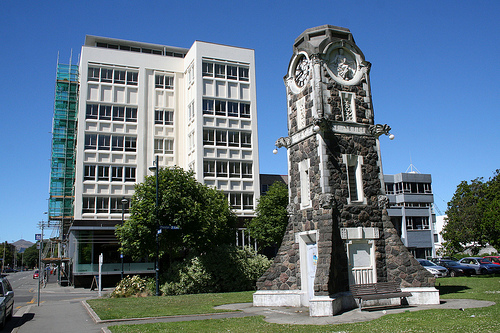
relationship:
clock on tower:
[284, 42, 370, 85] [241, 21, 437, 308]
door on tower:
[295, 231, 322, 313] [241, 21, 437, 308]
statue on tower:
[371, 117, 391, 141] [241, 21, 437, 308]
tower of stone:
[241, 21, 437, 308] [259, 240, 293, 288]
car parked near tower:
[3, 269, 15, 327] [241, 21, 437, 308]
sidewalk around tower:
[8, 284, 491, 332] [241, 21, 437, 308]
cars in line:
[420, 248, 498, 275] [414, 237, 493, 269]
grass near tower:
[105, 273, 490, 332] [241, 21, 437, 308]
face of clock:
[292, 65, 308, 81] [284, 42, 370, 85]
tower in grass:
[241, 21, 437, 308] [105, 273, 490, 332]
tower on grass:
[241, 21, 437, 308] [105, 273, 490, 332]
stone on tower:
[259, 240, 293, 288] [241, 21, 437, 308]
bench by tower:
[350, 281, 411, 306] [241, 21, 437, 308]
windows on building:
[88, 60, 235, 213] [53, 34, 463, 275]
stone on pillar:
[259, 240, 293, 288] [318, 200, 341, 294]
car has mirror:
[3, 269, 15, 327] [6, 286, 13, 299]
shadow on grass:
[433, 285, 479, 295] [105, 273, 490, 332]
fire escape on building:
[54, 71, 71, 287] [53, 34, 463, 275]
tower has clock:
[241, 21, 437, 308] [284, 42, 370, 85]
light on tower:
[271, 128, 291, 157] [241, 21, 437, 308]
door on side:
[295, 231, 322, 313] [276, 34, 326, 297]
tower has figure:
[241, 21, 437, 308] [336, 48, 358, 78]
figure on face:
[336, 48, 358, 78] [324, 46, 366, 73]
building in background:
[53, 34, 463, 275] [5, 2, 495, 286]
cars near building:
[420, 248, 498, 275] [53, 34, 463, 275]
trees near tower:
[120, 167, 284, 248] [241, 21, 437, 308]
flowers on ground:
[116, 278, 154, 293] [97, 298, 200, 316]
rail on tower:
[345, 269, 376, 286] [241, 21, 437, 308]